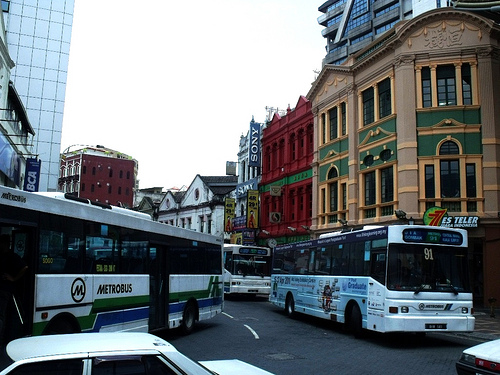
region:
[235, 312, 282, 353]
white line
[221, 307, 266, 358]
white line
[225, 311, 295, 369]
white line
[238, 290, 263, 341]
white line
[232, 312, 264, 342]
white line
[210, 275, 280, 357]
white line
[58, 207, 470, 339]
Buses on the street.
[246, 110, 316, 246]
A tall red building.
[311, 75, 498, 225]
A green and gold building sits on the corner.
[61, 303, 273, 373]
A white car next to the bus.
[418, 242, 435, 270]
The bus has number 91 on the windshield.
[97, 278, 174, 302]
The bus have "metrobus" written on the side.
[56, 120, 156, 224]
the brick red building has windows.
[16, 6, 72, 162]
The building is covered with glass stained windows.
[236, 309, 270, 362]
A white line in the street.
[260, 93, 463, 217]
The red building is next to the gold building.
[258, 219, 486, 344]
bus on a street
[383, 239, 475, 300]
front windshield on a bus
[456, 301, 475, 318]
front headlight on a bus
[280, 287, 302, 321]
rear wheel on a bus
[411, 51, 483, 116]
windows on a building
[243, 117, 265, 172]
blue and white sign on a building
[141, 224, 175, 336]
side door on a bus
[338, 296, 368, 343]
front wheel on a bus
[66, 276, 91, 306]
logo on the side of a bus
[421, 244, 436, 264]
number on the front of a bus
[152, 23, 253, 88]
Cloudy sky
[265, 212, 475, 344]
A city bus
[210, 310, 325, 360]
a street full of vehicles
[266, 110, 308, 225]
an old style red building.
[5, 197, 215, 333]
A bus green, blue stripes.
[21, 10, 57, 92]
A glass window on building.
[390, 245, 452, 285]
A bus window shield.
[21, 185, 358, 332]
Three city buses on a road way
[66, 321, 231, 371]
A white car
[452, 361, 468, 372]
Front pumper of a car.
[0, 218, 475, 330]
three public transportation buses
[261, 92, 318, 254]
a red building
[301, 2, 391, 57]
a tall building with with windows and balconies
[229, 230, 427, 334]
two buses going the same direction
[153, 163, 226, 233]
a white building with pointed roof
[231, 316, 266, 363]
white line painted on road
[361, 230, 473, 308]
windshield on a bus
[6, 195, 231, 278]
long side windows on a bus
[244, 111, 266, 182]
a blue and white sign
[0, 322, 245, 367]
roof of a white car